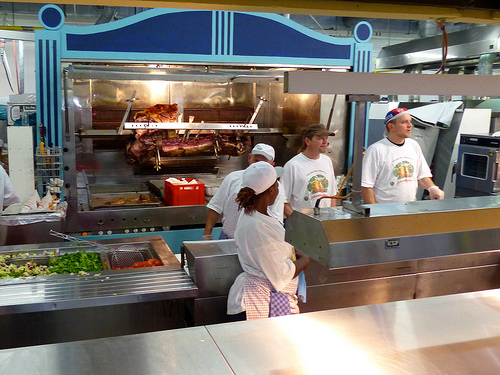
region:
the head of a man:
[380, 91, 441, 148]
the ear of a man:
[372, 110, 398, 145]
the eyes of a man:
[394, 112, 421, 135]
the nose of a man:
[392, 101, 428, 141]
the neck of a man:
[380, 122, 410, 157]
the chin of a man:
[396, 127, 423, 148]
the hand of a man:
[412, 174, 454, 204]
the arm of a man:
[409, 135, 459, 201]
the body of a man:
[351, 103, 464, 208]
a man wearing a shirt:
[349, 90, 446, 196]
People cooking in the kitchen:
[236, 130, 433, 223]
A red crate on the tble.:
[156, 173, 204, 206]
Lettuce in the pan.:
[7, 240, 101, 268]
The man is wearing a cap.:
[293, 115, 343, 146]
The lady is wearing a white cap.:
[220, 168, 280, 196]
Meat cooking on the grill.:
[118, 115, 233, 160]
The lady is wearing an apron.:
[216, 267, 323, 307]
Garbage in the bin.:
[11, 185, 68, 225]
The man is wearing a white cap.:
[241, 141, 278, 161]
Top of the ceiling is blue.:
[49, 18, 381, 84]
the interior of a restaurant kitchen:
[0, 0, 498, 374]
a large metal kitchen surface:
[0, 288, 499, 374]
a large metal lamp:
[284, 194, 499, 270]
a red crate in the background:
[162, 176, 204, 206]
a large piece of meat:
[124, 103, 246, 163]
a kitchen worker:
[226, 160, 310, 322]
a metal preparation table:
[0, 233, 198, 315]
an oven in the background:
[450, 133, 498, 198]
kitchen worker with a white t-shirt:
[202, 143, 284, 241]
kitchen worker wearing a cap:
[360, 107, 443, 204]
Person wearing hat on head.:
[381, 91, 415, 129]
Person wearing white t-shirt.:
[363, 150, 422, 192]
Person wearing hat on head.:
[304, 117, 330, 131]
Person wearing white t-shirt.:
[294, 160, 340, 210]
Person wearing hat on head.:
[250, 142, 282, 162]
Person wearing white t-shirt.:
[216, 183, 240, 219]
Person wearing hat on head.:
[236, 162, 261, 181]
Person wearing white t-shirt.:
[235, 205, 292, 284]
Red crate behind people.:
[165, 173, 210, 209]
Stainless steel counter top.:
[204, 338, 396, 360]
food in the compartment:
[80, 255, 93, 272]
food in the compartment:
[35, 261, 54, 275]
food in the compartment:
[136, 255, 167, 270]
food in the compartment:
[18, 258, 29, 281]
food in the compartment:
[10, 263, 20, 275]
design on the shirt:
[305, 174, 327, 196]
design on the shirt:
[398, 160, 415, 182]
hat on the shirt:
[308, 125, 335, 140]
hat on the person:
[249, 136, 274, 161]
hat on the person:
[242, 161, 282, 189]